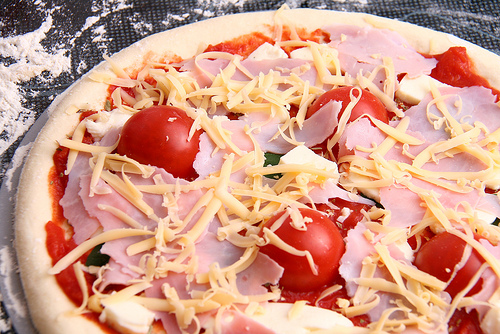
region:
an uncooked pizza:
[25, 25, 498, 326]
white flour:
[0, 0, 81, 145]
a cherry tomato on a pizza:
[123, 101, 203, 176]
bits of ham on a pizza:
[216, 106, 346, 154]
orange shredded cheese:
[112, 166, 232, 266]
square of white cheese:
[100, 286, 150, 327]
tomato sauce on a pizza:
[46, 148, 76, 283]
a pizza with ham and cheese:
[25, 22, 495, 327]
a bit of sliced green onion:
[81, 240, 109, 266]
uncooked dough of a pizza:
[122, 2, 332, 44]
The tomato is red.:
[243, 204, 346, 274]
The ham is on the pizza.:
[243, 103, 351, 153]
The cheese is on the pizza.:
[25, 15, 495, 326]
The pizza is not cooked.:
[4, 4, 448, 331]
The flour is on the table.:
[5, 12, 53, 117]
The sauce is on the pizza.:
[27, 144, 107, 321]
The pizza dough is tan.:
[15, 64, 93, 326]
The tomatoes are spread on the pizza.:
[93, 46, 494, 301]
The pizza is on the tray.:
[10, 2, 492, 322]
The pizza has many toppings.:
[4, 2, 492, 330]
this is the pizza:
[20, 37, 499, 332]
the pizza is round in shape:
[13, 20, 496, 330]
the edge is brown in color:
[38, 290, 63, 320]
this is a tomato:
[276, 216, 341, 276]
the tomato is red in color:
[310, 225, 330, 256]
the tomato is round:
[117, 98, 203, 178]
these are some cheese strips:
[98, 176, 230, 298]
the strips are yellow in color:
[163, 229, 193, 276]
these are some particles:
[2, 39, 44, 71]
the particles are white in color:
[1, 71, 17, 124]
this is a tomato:
[122, 112, 188, 162]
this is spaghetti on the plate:
[203, 158, 279, 231]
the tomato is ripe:
[127, 110, 185, 156]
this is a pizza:
[25, 177, 59, 220]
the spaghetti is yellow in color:
[387, 127, 462, 187]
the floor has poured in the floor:
[2, 26, 59, 75]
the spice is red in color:
[49, 232, 71, 254]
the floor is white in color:
[2, 22, 72, 71]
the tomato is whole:
[283, 219, 340, 283]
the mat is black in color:
[422, 5, 439, 24]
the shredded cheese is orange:
[200, 133, 282, 246]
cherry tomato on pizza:
[93, 110, 226, 205]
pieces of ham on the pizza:
[81, 184, 228, 281]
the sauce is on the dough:
[41, 173, 123, 303]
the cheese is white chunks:
[289, 147, 337, 178]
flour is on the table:
[5, 15, 109, 159]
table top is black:
[42, 10, 139, 52]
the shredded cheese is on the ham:
[98, 178, 238, 267]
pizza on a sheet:
[8, 125, 45, 184]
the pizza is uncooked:
[73, 56, 497, 309]